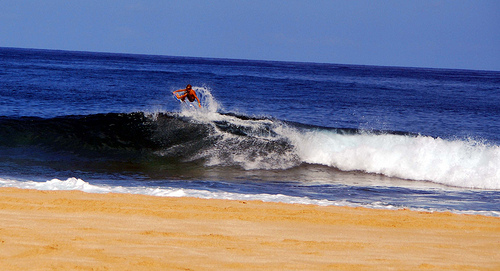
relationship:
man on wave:
[171, 84, 202, 111] [1, 105, 498, 190]